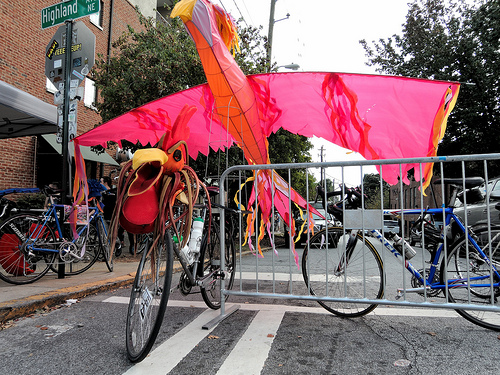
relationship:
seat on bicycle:
[434, 176, 485, 190] [300, 181, 497, 337]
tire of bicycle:
[126, 229, 172, 363] [100, 141, 236, 363]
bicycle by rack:
[335, 226, 486, 296] [231, 146, 466, 306]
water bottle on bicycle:
[388, 227, 422, 275] [285, 161, 488, 322]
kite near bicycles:
[49, 0, 475, 267] [104, 132, 496, 370]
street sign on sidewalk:
[38, 0, 103, 275] [2, 230, 262, 328]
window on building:
[80, 75, 99, 105] [2, 0, 179, 242]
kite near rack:
[49, 0, 475, 267] [219, 151, 499, 318]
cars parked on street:
[383, 168, 489, 288] [3, 228, 498, 372]